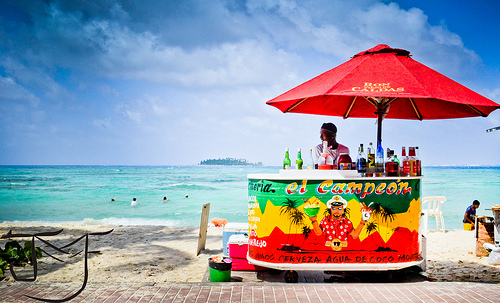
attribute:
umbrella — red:
[265, 44, 499, 148]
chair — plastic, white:
[421, 194, 448, 232]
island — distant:
[200, 157, 263, 166]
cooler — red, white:
[229, 234, 268, 271]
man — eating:
[462, 200, 479, 230]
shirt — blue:
[462, 206, 475, 223]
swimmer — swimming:
[111, 197, 116, 202]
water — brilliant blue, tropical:
[1, 165, 500, 226]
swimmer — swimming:
[130, 197, 138, 206]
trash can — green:
[209, 256, 231, 282]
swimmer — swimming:
[163, 195, 168, 203]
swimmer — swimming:
[185, 194, 189, 199]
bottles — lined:
[283, 139, 421, 176]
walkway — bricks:
[0, 280, 499, 302]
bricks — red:
[1, 279, 500, 302]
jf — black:
[0, 229, 114, 302]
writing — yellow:
[352, 81, 404, 92]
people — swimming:
[110, 193, 188, 206]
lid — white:
[228, 234, 248, 245]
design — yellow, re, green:
[247, 179, 421, 264]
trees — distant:
[198, 158, 263, 165]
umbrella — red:
[267, 43, 500, 120]